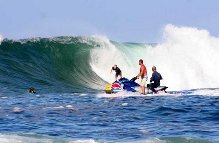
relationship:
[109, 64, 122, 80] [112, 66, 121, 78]
man wearing wet suit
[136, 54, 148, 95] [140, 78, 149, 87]
man wearing shorts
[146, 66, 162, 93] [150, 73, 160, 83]
man wearing shirt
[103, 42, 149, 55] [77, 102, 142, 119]
color inside of water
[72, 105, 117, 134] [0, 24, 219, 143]
waters are inside of waters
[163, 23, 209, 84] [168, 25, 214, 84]
waves are inside of section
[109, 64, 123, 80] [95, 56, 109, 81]
man riding on wave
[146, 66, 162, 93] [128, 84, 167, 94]
man riding on ski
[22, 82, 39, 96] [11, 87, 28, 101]
person inside of water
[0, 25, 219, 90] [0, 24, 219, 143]
waves inside of waters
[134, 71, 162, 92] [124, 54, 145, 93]
shorts on man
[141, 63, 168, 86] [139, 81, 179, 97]
man on jet ski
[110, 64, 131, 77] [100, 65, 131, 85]
shirt on surfer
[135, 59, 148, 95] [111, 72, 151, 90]
man on jet ski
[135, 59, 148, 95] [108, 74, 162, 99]
man on jet ski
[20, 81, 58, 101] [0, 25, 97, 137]
object on water